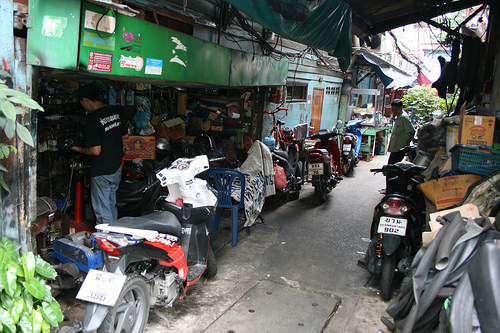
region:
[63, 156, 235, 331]
a small motorbike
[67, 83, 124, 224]
a man is standing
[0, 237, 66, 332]
a plant with green leaves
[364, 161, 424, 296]
a small black motorbike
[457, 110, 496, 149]
a box made of cardboard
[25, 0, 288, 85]
green metal on a wall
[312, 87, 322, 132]
a door made of wood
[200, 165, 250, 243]
chair is blue and made of plastic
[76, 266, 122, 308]
a license plate for a bike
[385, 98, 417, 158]
a man is standing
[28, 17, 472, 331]
Outdoor type of market.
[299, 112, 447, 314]
Motorcycle on the road.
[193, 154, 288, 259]
Chair on the road.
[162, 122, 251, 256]
Blue chair on the ground.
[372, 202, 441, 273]
Plate on the bike.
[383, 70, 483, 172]
Green leaves on the tree.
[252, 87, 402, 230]
Door on a building.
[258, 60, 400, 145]
Windows on the building.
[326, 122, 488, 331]
Black motorcycle.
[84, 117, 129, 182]
the shirt is black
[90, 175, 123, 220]
the jeans are blue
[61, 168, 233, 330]
the bike is black and white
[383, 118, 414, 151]
the shirt is green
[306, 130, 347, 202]
the bike is red in color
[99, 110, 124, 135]
white writing is on the shirt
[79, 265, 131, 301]
the numberplate is white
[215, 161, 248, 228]
the chair is blue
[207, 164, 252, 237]
the chair is plastic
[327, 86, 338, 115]
the wall is blue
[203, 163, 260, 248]
dark blue plastic chair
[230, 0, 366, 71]
green tarp hanging overhead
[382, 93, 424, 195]
man leaning on table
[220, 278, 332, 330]
holes in cement plate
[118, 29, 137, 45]
heart on green overhang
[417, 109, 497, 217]
cardboard boxes on table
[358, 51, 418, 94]
blue tarp used as canopy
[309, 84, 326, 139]
brown wooden door in building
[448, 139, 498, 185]
light blue basket on table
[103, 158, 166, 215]
black hose wound around machine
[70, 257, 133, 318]
White License plate on scooter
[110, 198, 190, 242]
black seat on a red scooter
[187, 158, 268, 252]
Blue plastic chair on concrete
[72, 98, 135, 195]
Man wearing a black shirt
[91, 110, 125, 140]
White writing on a black shirt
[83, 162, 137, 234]
Man wearing blue jeans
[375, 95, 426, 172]
Man in green shirt standing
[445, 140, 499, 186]
Blue plastic hamper on a cardboard box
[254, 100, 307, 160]
Bicycle laying against a green wall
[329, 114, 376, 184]
Blue scooter parked on under a green tarp